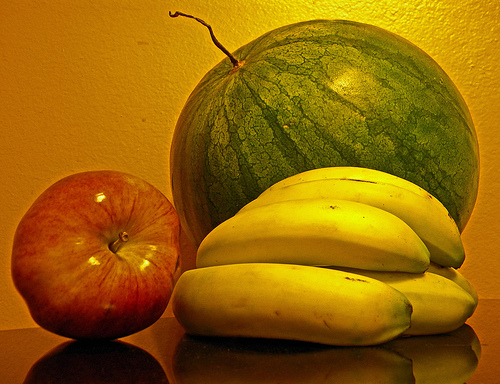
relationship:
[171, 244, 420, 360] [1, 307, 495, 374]
banana on table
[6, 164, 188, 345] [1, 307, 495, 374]
apple on table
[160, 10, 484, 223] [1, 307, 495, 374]
watermelon on table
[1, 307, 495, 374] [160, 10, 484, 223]
table under watermelon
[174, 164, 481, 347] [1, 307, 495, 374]
bananas on table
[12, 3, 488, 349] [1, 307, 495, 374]
fruit on table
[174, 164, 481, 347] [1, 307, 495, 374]
bananas are on top of table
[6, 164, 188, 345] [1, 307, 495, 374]
apple on top of table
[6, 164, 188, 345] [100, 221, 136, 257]
apple has stem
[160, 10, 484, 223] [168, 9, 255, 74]
watermelon has stem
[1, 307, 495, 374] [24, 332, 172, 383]
table has reflection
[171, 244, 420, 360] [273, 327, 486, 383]
banana has reflection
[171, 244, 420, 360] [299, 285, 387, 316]
banana has skin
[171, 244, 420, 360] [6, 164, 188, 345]
banana next to apple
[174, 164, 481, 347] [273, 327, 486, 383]
bananas have reflection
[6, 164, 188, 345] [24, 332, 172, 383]
apple has reflection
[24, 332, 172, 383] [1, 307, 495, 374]
reflection on table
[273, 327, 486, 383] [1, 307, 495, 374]
reflection on table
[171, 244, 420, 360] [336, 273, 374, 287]
banana has spot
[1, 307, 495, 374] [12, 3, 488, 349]
table beneath fruit